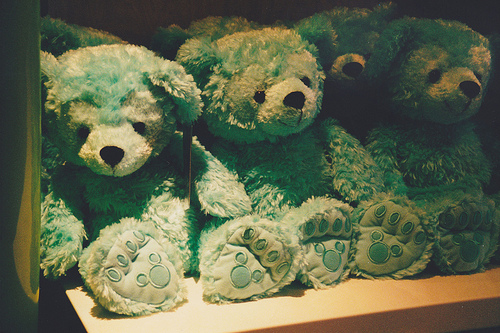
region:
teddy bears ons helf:
[76, 153, 482, 278]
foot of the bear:
[39, 222, 194, 303]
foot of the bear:
[185, 205, 297, 292]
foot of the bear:
[299, 189, 366, 298]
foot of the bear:
[335, 175, 424, 275]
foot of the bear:
[444, 193, 480, 270]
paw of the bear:
[203, 178, 263, 217]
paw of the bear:
[49, 223, 90, 276]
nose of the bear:
[105, 145, 127, 164]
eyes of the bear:
[73, 116, 150, 136]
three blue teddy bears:
[18, 19, 495, 321]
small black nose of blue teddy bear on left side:
[97, 141, 124, 165]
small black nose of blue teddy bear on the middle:
[283, 88, 304, 112]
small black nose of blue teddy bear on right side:
[457, 78, 482, 101]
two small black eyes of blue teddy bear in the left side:
[71, 115, 151, 136]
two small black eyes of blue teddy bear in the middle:
[253, 73, 312, 108]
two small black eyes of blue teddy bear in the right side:
[428, 64, 488, 86]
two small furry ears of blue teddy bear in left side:
[36, 43, 198, 120]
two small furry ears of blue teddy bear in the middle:
[183, 13, 337, 88]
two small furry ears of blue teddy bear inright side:
[358, 28, 498, 73]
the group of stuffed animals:
[32, 0, 498, 315]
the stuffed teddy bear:
[32, 43, 300, 315]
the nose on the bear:
[100, 145, 123, 164]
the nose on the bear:
[282, 91, 305, 110]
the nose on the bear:
[340, 62, 364, 77]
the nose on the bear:
[460, 80, 481, 98]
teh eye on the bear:
[77, 124, 90, 137]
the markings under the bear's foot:
[105, 229, 170, 287]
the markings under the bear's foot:
[229, 226, 287, 288]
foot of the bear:
[72, 218, 166, 296]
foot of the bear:
[200, 233, 278, 300]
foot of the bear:
[272, 55, 360, 284]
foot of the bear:
[354, 194, 429, 279]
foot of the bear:
[425, 173, 488, 278]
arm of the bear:
[22, 220, 92, 275]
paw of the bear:
[192, 182, 214, 204]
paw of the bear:
[330, 147, 375, 200]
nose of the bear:
[105, 143, 114, 180]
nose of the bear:
[267, 83, 299, 117]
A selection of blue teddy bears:
[26, 20, 484, 322]